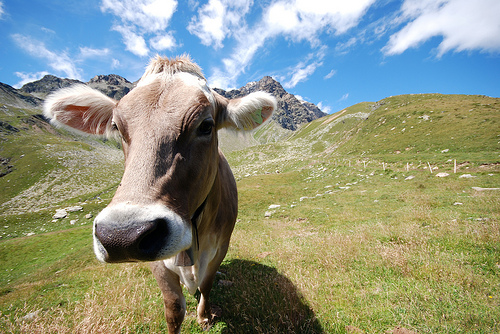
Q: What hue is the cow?
A: Brown and white.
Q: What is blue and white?
A: The sky.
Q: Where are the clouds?
A: In the sky.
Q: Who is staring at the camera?
A: The cow.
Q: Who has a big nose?
A: The cow.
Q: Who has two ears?
A: The cow.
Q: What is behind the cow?
A: Mountain.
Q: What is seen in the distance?
A: Mountain.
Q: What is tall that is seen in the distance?
A: Mountain.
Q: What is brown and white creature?
A: Cow.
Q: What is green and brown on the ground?
A: Grass.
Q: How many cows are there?
A: One.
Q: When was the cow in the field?
A: Daytime.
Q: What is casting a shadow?
A: The cow.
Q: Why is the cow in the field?
A: To graze.